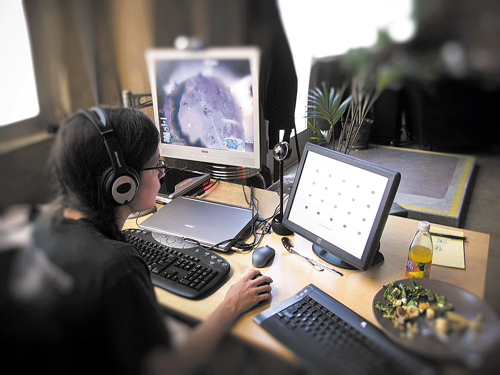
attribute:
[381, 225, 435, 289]
beverage — yellow, full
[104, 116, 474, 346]
desk — wood, computer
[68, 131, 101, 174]
hair — brown, dark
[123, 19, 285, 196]
monitor — desktop, silver, black, gray, computer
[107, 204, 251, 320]
keyboard — black, silver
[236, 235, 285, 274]
mouse — black, wireless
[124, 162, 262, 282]
laptop — silver, black, gray, closed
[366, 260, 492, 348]
food — dark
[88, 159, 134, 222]
headphone — silver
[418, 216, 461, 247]
notepad — yellow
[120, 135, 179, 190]
glasses — framed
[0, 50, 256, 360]
woman — wearing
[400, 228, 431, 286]
liquid — yellow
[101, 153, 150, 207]
earphone — black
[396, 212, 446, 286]
drink — yellow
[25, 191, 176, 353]
shirt — black